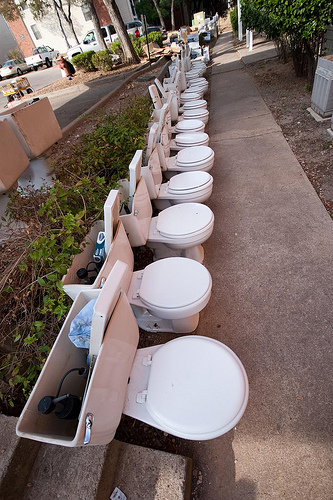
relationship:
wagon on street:
[5, 37, 49, 98] [41, 63, 75, 113]